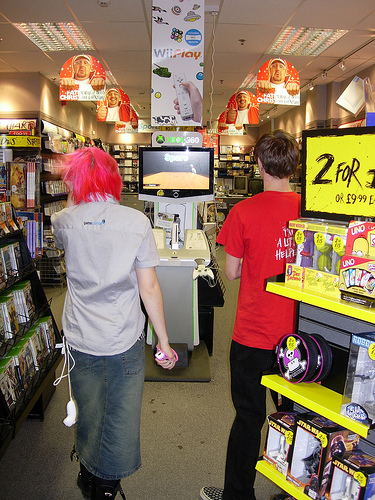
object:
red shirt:
[214, 189, 296, 353]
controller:
[56, 332, 79, 429]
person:
[45, 145, 184, 498]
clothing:
[50, 186, 161, 394]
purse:
[273, 331, 318, 386]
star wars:
[255, 410, 296, 483]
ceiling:
[218, 5, 374, 105]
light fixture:
[266, 14, 350, 77]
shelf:
[264, 274, 375, 325]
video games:
[19, 278, 36, 325]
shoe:
[195, 486, 239, 499]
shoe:
[96, 466, 129, 500]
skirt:
[64, 341, 148, 484]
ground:
[309, 98, 362, 156]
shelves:
[0, 143, 63, 442]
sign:
[151, 130, 203, 149]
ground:
[311, 63, 339, 102]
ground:
[281, 74, 328, 116]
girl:
[49, 144, 177, 500]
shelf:
[260, 371, 375, 442]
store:
[0, 0, 375, 500]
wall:
[185, 70, 239, 97]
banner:
[150, 5, 205, 130]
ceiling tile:
[222, 18, 249, 42]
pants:
[212, 339, 277, 500]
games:
[0, 355, 23, 414]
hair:
[58, 145, 124, 203]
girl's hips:
[63, 323, 138, 354]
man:
[200, 125, 302, 497]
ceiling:
[12, 28, 152, 123]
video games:
[0, 292, 22, 345]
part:
[301, 390, 325, 406]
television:
[136, 146, 214, 201]